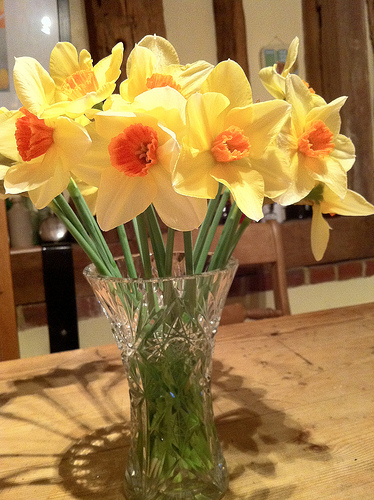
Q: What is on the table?
A: A vase.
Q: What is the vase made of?
A: Glass.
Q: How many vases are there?
A: One.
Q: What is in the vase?
A: Flowers.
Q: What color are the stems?
A: Green.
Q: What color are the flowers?
A: Yellow and orange.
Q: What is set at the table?
A: A chair.